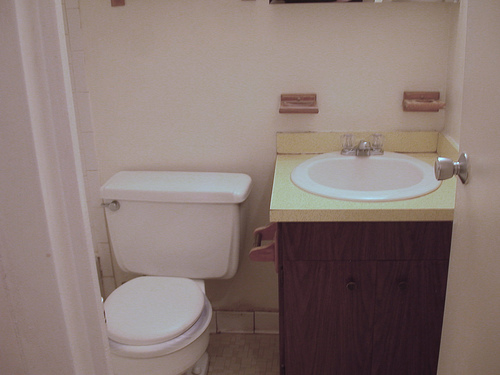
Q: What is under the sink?
A: Brown cabinet.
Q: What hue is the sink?
A: White.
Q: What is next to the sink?
A: Toilet.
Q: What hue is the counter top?
A: Yellow.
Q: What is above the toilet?
A: White wall.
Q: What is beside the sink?
A: A toilet.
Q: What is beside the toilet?
A: Sink.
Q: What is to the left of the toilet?
A: A curtain.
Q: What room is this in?
A: A bathroom.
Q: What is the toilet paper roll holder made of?
A: Wood.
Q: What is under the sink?
A: A cabinet.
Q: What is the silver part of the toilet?
A: The flush.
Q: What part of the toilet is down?
A: The lid.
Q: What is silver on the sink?
A: The faucet.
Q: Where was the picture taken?
A: A restroom.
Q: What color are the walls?
A: White.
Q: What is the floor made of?
A: Tile.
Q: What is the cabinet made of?
A: Wood.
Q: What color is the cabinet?
A: Brown.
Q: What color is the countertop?
A: Yellow.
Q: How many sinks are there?
A: One.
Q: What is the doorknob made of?
A: Metal.